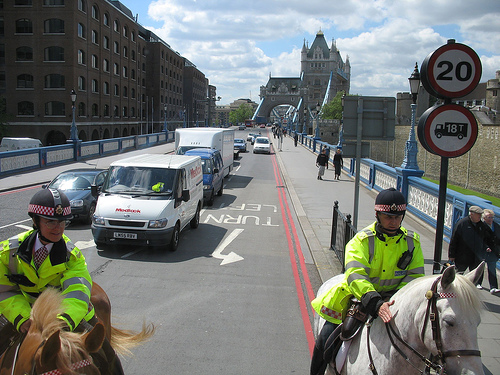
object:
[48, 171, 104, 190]
window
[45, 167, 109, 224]
car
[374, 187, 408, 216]
helmet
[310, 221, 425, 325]
safety jacket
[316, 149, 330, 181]
people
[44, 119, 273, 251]
traffic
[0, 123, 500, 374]
bridge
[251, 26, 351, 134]
structure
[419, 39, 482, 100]
sign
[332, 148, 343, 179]
pedestrians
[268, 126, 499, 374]
sidewalk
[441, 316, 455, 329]
eye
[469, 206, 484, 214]
hat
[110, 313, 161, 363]
tail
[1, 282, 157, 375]
horse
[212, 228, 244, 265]
arrow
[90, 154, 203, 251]
van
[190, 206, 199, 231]
tire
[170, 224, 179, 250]
tire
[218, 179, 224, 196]
tire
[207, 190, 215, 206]
tire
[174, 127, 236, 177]
van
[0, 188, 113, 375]
officer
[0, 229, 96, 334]
coat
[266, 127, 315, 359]
lines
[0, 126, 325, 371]
lane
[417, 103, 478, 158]
sign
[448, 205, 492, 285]
people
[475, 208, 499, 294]
people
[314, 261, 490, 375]
horse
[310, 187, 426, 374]
cop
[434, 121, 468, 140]
18t truck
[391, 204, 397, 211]
badge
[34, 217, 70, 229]
glasses